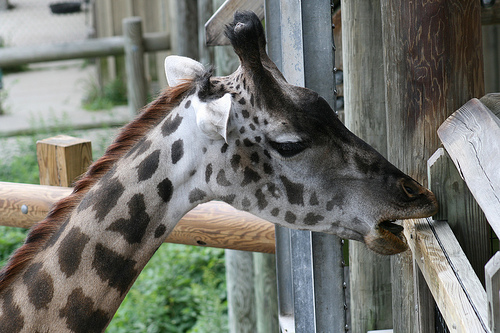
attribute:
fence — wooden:
[276, 15, 490, 326]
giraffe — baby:
[0, 60, 450, 317]